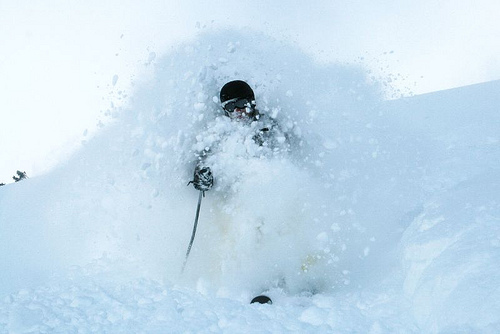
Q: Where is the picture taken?
A: Ski slope.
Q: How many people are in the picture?
A: One.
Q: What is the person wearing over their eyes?
A: Goggles.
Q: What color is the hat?
A: Black.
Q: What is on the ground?
A: Snow.